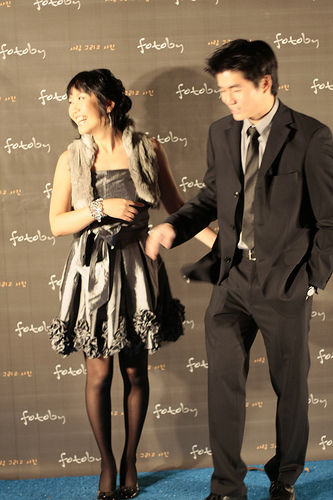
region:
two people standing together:
[50, 43, 328, 281]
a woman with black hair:
[64, 52, 157, 242]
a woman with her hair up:
[51, 38, 188, 227]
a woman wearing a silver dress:
[46, 38, 202, 380]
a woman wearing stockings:
[12, 76, 148, 428]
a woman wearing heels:
[52, 83, 194, 485]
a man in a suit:
[179, 42, 324, 345]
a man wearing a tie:
[157, 8, 311, 341]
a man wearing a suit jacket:
[212, 36, 288, 378]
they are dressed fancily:
[43, 25, 331, 498]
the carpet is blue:
[6, 449, 327, 496]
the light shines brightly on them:
[42, 21, 316, 221]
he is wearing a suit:
[182, 27, 322, 498]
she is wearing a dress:
[40, 111, 201, 367]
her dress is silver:
[44, 63, 219, 372]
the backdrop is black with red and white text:
[0, 0, 329, 232]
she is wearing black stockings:
[70, 334, 172, 499]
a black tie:
[239, 122, 268, 253]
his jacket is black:
[151, 93, 330, 293]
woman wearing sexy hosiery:
[47, 68, 183, 498]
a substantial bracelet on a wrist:
[89, 197, 103, 222]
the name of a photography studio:
[17, 408, 67, 427]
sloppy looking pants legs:
[207, 453, 307, 496]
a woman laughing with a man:
[66, 67, 134, 135]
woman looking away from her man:
[66, 66, 131, 139]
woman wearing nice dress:
[51, 68, 184, 498]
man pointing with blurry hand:
[141, 216, 176, 240]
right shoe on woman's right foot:
[90, 476, 123, 499]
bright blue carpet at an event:
[159, 472, 185, 494]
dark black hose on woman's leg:
[88, 366, 113, 449]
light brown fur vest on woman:
[126, 138, 167, 208]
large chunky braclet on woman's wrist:
[93, 193, 116, 226]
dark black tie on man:
[242, 121, 266, 265]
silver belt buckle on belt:
[244, 240, 260, 271]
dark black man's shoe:
[197, 486, 237, 499]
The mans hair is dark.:
[202, 35, 286, 96]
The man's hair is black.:
[203, 33, 294, 96]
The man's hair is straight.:
[199, 39, 291, 93]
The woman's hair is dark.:
[63, 63, 140, 135]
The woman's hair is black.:
[60, 62, 138, 134]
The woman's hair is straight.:
[69, 65, 136, 129]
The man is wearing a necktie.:
[241, 124, 266, 253]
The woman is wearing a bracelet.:
[87, 198, 116, 217]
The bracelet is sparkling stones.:
[84, 195, 109, 228]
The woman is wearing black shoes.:
[94, 479, 144, 498]